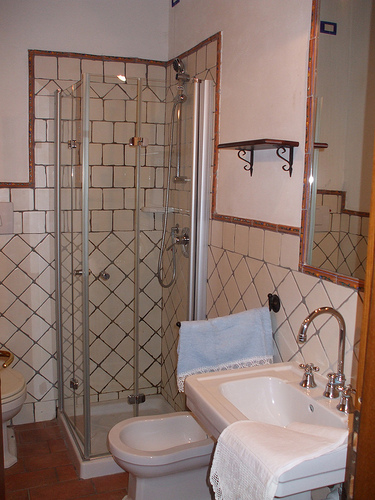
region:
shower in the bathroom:
[57, 72, 211, 442]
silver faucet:
[283, 304, 355, 411]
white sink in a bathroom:
[176, 296, 356, 445]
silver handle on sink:
[292, 355, 322, 395]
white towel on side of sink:
[197, 421, 327, 498]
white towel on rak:
[176, 304, 276, 379]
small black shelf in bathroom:
[192, 128, 301, 187]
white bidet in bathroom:
[109, 407, 199, 484]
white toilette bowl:
[0, 354, 43, 469]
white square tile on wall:
[36, 97, 119, 243]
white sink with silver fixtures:
[188, 297, 358, 485]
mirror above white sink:
[302, 6, 372, 287]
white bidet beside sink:
[106, 408, 213, 496]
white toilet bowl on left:
[2, 346, 25, 471]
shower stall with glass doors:
[48, 66, 188, 451]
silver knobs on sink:
[297, 357, 354, 415]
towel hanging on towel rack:
[169, 310, 274, 383]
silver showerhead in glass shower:
[164, 49, 192, 81]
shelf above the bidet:
[211, 127, 295, 176]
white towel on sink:
[201, 416, 345, 499]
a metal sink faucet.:
[296, 270, 349, 398]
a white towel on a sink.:
[200, 413, 354, 499]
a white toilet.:
[93, 393, 213, 498]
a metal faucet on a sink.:
[288, 332, 326, 400]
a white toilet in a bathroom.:
[0, 352, 40, 472]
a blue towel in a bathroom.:
[168, 278, 287, 395]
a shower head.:
[154, 56, 214, 108]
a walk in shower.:
[32, 58, 208, 484]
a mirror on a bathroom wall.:
[285, 5, 373, 291]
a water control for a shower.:
[164, 212, 200, 247]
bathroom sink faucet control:
[294, 359, 324, 391]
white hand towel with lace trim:
[207, 415, 360, 498]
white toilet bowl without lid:
[109, 412, 212, 487]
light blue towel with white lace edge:
[170, 305, 273, 388]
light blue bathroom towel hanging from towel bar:
[167, 307, 283, 390]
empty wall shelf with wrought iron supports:
[213, 137, 311, 181]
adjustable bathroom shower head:
[145, 49, 201, 291]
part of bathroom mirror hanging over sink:
[297, 28, 373, 279]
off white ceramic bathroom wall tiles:
[210, 231, 297, 289]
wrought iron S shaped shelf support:
[273, 145, 294, 175]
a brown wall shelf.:
[215, 129, 300, 178]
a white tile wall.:
[209, 243, 284, 288]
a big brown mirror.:
[295, 2, 372, 290]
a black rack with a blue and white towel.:
[172, 283, 277, 363]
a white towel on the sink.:
[206, 412, 356, 497]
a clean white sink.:
[181, 304, 356, 494]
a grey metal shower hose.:
[145, 53, 199, 291]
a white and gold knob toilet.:
[0, 335, 47, 475]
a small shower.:
[46, 49, 214, 453]